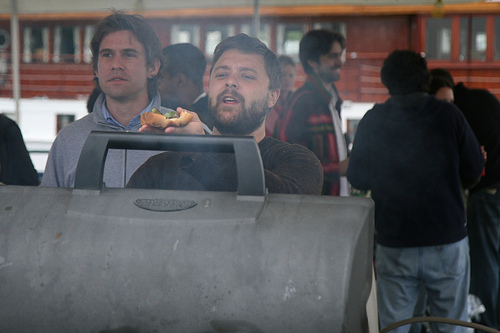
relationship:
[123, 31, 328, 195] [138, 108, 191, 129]
man holding bun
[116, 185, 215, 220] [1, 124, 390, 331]
emblem center of grill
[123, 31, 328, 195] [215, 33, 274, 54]
man has hair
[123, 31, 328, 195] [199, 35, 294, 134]
man has head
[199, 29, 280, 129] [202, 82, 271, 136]
face has beard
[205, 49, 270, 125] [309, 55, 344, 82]
face has beard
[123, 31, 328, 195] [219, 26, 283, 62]
man has hair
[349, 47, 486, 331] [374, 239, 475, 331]
man wearing jeans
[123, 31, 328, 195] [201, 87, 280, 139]
man with beard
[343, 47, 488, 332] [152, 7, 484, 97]
man in background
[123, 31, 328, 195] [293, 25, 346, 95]
man with beard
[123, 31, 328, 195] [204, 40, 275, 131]
man with face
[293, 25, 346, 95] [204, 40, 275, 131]
beard on face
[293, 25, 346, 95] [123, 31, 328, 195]
beard on man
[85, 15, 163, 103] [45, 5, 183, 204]
head of person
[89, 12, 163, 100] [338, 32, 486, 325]
head of person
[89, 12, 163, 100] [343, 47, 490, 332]
head of person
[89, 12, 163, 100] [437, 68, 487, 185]
head of person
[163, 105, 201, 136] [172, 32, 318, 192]
hand of man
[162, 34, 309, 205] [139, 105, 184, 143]
man has bun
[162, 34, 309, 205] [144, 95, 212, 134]
man has hand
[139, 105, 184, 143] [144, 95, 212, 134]
bun in hand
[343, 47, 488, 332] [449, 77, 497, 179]
man wears shirt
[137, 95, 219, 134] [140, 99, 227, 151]
sandwich in hand